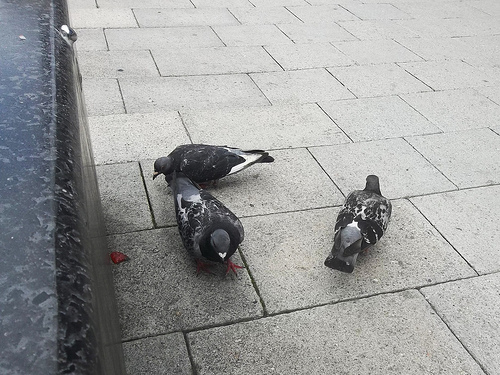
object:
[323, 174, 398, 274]
pigeons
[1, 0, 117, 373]
marble wall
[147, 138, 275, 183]
pigeon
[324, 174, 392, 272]
pigeon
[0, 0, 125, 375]
stone curb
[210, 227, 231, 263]
head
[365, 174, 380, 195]
head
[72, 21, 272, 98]
pavers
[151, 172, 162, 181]
beak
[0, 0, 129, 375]
curb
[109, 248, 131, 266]
pedaql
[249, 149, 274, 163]
tail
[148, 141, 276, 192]
bird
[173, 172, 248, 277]
bird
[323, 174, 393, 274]
bird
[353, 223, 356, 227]
white feathers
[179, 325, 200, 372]
crack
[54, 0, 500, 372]
tile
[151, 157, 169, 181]
head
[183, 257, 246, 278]
claws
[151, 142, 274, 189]
dove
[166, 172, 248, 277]
dove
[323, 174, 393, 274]
dove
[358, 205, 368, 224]
stripes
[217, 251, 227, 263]
beak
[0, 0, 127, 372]
divider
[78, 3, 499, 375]
slabs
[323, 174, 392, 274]
feathers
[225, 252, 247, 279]
leg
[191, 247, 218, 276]
leg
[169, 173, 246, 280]
pigeon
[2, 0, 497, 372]
ground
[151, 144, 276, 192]
birds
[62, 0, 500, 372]
floor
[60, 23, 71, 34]
droppings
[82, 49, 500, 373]
sidewalk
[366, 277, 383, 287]
food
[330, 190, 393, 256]
wing